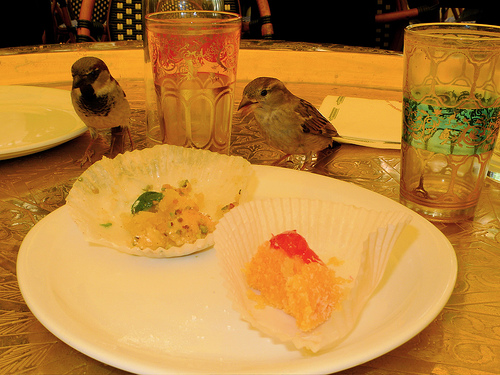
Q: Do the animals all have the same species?
A: Yes, all the animals are birds.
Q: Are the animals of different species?
A: No, all the animals are birds.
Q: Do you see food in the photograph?
A: Yes, there is food.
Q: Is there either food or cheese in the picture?
A: Yes, there is food.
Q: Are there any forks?
A: No, there are no forks.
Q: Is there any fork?
A: No, there are no forks.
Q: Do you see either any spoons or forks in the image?
A: No, there are no forks or spoons.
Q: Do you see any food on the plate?
A: Yes, there is food on the plate.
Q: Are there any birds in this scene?
A: Yes, there are birds.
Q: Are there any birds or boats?
A: Yes, there are birds.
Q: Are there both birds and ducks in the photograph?
A: No, there are birds but no ducks.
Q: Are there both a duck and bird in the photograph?
A: No, there are birds but no ducks.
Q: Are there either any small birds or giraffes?
A: Yes, there are small birds.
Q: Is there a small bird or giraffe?
A: Yes, there are small birds.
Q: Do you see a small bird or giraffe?
A: Yes, there are small birds.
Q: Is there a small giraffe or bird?
A: Yes, there are small birds.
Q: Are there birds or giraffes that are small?
A: Yes, the birds are small.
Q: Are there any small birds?
A: Yes, there are small birds.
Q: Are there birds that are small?
A: Yes, there are birds that are small.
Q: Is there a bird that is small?
A: Yes, there are birds that are small.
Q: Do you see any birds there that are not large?
A: Yes, there are small birds.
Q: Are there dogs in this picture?
A: No, there are no dogs.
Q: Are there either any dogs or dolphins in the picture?
A: No, there are no dogs or dolphins.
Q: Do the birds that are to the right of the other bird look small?
A: Yes, the birds are small.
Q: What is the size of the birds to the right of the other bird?
A: The birds are small.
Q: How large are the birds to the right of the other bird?
A: The birds are small.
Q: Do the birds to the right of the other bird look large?
A: No, the birds are small.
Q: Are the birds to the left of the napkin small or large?
A: The birds are small.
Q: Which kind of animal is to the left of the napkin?
A: The animals are birds.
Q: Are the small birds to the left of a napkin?
A: Yes, the birds are to the left of a napkin.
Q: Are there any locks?
A: No, there are no locks.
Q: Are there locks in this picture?
A: No, there are no locks.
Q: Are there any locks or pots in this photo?
A: No, there are no locks or pots.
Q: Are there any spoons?
A: No, there are no spoons.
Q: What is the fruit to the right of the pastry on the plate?
A: The fruit is a cherry.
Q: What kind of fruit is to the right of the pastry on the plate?
A: The fruit is a cherry.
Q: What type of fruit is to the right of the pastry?
A: The fruit is a cherry.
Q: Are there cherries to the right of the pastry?
A: Yes, there is a cherry to the right of the pastry.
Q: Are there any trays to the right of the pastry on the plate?
A: No, there is a cherry to the right of the pastry.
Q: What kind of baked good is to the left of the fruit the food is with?
A: The food is a pastry.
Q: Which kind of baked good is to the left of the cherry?
A: The food is a pastry.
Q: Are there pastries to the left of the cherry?
A: Yes, there is a pastry to the left of the cherry.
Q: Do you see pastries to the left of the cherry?
A: Yes, there is a pastry to the left of the cherry.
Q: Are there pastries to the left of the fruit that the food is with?
A: Yes, there is a pastry to the left of the cherry.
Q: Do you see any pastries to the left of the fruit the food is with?
A: Yes, there is a pastry to the left of the cherry.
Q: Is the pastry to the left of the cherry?
A: Yes, the pastry is to the left of the cherry.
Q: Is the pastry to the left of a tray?
A: No, the pastry is to the left of the cherry.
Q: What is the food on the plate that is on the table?
A: The food is a pastry.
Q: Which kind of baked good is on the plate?
A: The food is a pastry.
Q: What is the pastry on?
A: The pastry is on the plate.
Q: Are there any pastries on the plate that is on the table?
A: Yes, there is a pastry on the plate.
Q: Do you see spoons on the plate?
A: No, there is a pastry on the plate.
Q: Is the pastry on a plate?
A: Yes, the pastry is on a plate.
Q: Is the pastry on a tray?
A: No, the pastry is on a plate.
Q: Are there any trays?
A: No, there are no trays.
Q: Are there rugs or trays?
A: No, there are no trays or rugs.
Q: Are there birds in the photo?
A: Yes, there is a bird.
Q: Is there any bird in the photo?
A: Yes, there is a bird.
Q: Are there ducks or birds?
A: Yes, there is a bird.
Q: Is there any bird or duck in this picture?
A: Yes, there is a bird.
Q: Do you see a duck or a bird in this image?
A: Yes, there is a bird.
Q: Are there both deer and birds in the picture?
A: No, there is a bird but no deer.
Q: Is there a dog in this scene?
A: No, there are no dogs.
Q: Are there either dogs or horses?
A: No, there are no dogs or horses.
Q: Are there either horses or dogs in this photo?
A: No, there are no dogs or horses.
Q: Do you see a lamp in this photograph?
A: No, there are no lamps.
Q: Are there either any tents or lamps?
A: No, there are no lamps or tents.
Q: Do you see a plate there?
A: Yes, there is a plate.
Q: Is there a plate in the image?
A: Yes, there is a plate.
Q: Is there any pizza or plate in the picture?
A: Yes, there is a plate.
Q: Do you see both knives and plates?
A: No, there is a plate but no knives.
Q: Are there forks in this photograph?
A: No, there are no forks.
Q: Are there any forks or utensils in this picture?
A: No, there are no forks or utensils.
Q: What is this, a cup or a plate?
A: This is a plate.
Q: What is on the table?
A: The plate is on the table.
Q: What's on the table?
A: The plate is on the table.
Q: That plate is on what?
A: The plate is on the table.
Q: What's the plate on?
A: The plate is on the table.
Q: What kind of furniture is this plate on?
A: The plate is on the table.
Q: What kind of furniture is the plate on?
A: The plate is on the table.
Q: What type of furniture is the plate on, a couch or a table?
A: The plate is on a table.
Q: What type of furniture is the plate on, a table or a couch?
A: The plate is on a table.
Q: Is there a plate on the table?
A: Yes, there is a plate on the table.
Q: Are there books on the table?
A: No, there is a plate on the table.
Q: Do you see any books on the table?
A: No, there is a plate on the table.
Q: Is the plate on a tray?
A: No, the plate is on the table.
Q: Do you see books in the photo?
A: No, there are no books.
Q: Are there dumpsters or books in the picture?
A: No, there are no books or dumpsters.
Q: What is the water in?
A: The water is in the glass.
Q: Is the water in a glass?
A: Yes, the water is in a glass.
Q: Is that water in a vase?
A: No, the water is in a glass.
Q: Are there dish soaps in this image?
A: No, there are no dish soaps.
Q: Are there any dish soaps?
A: No, there are no dish soaps.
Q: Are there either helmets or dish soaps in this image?
A: No, there are no dish soaps or helmets.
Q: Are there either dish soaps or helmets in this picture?
A: No, there are no dish soaps or helmets.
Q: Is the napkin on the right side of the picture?
A: Yes, the napkin is on the right of the image.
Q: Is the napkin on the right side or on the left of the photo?
A: The napkin is on the right of the image.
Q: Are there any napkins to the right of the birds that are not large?
A: Yes, there is a napkin to the right of the birds.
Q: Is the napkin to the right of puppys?
A: No, the napkin is to the right of the birds.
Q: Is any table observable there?
A: Yes, there is a table.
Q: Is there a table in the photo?
A: Yes, there is a table.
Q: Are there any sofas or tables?
A: Yes, there is a table.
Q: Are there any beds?
A: No, there are no beds.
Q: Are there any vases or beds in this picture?
A: No, there are no beds or vases.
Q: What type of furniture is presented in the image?
A: The furniture is a table.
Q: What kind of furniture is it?
A: The piece of furniture is a table.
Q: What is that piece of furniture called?
A: That is a table.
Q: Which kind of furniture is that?
A: That is a table.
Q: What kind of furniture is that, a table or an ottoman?
A: That is a table.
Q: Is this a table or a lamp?
A: This is a table.